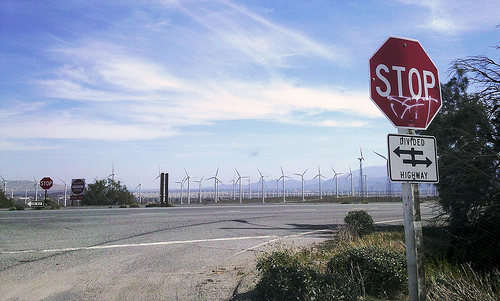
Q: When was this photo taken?
A: During the day.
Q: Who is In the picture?
A: No one.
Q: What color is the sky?
A: Blue.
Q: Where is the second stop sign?
A: Across the road.